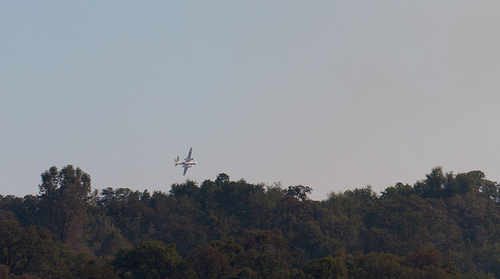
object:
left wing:
[184, 147, 192, 162]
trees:
[5, 160, 497, 277]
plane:
[173, 145, 198, 176]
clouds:
[328, 21, 455, 96]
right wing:
[181, 165, 187, 176]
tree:
[47, 167, 89, 244]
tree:
[115, 238, 188, 277]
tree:
[276, 189, 301, 241]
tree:
[402, 205, 429, 258]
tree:
[195, 178, 244, 253]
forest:
[1, 165, 498, 277]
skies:
[278, 72, 433, 149]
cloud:
[146, 79, 233, 107]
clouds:
[237, 82, 448, 158]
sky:
[1, 2, 493, 192]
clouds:
[248, 71, 293, 126]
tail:
[173, 157, 179, 167]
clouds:
[190, 17, 498, 167]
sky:
[94, 106, 429, 198]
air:
[138, 121, 228, 179]